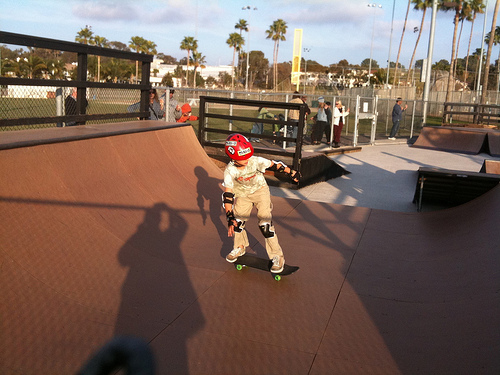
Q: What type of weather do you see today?
A: It is cloudy.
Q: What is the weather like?
A: It is cloudy.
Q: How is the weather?
A: It is cloudy.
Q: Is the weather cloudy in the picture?
A: Yes, it is cloudy.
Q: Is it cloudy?
A: Yes, it is cloudy.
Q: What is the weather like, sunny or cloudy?
A: It is cloudy.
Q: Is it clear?
A: No, it is cloudy.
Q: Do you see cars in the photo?
A: No, there are no cars.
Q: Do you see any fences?
A: Yes, there is a fence.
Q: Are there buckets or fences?
A: Yes, there is a fence.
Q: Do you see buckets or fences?
A: Yes, there is a fence.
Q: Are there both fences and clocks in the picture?
A: No, there is a fence but no clocks.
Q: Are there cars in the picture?
A: No, there are no cars.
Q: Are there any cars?
A: No, there are no cars.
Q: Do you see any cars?
A: No, there are no cars.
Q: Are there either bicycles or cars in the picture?
A: No, there are no cars or bicycles.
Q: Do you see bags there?
A: No, there are no bags.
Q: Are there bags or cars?
A: No, there are no bags or cars.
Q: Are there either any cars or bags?
A: No, there are no bags or cars.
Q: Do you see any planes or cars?
A: No, there are no cars or planes.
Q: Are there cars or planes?
A: No, there are no cars or planes.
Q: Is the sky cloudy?
A: Yes, the sky is cloudy.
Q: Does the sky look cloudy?
A: Yes, the sky is cloudy.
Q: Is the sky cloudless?
A: No, the sky is cloudy.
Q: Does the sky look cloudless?
A: No, the sky is cloudy.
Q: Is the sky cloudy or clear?
A: The sky is cloudy.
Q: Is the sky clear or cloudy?
A: The sky is cloudy.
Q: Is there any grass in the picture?
A: Yes, there is grass.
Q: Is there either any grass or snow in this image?
A: Yes, there is grass.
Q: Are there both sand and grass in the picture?
A: No, there is grass but no sand.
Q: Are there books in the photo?
A: No, there are no books.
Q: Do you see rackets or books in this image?
A: No, there are no books or rackets.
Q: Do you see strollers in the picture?
A: No, there are no strollers.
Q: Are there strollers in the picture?
A: No, there are no strollers.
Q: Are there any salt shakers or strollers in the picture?
A: No, there are no strollers or salt shakers.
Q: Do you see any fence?
A: Yes, there is a fence.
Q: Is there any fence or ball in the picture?
A: Yes, there is a fence.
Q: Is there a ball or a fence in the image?
A: Yes, there is a fence.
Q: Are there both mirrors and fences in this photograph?
A: No, there is a fence but no mirrors.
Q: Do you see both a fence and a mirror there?
A: No, there is a fence but no mirrors.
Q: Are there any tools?
A: No, there are no tools.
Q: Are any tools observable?
A: No, there are no tools.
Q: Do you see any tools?
A: No, there are no tools.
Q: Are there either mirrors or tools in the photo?
A: No, there are no tools or mirrors.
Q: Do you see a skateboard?
A: Yes, there is a skateboard.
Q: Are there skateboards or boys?
A: Yes, there is a skateboard.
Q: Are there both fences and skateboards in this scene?
A: Yes, there are both a skateboard and a fence.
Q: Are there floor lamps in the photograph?
A: No, there are no floor lamps.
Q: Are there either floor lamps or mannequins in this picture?
A: No, there are no floor lamps or mannequins.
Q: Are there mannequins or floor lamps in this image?
A: No, there are no floor lamps or mannequins.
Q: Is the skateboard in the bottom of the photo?
A: Yes, the skateboard is in the bottom of the image.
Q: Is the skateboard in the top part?
A: No, the skateboard is in the bottom of the image.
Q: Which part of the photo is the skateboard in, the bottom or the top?
A: The skateboard is in the bottom of the image.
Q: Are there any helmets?
A: Yes, there is a helmet.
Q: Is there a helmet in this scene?
A: Yes, there is a helmet.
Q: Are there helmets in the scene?
A: Yes, there is a helmet.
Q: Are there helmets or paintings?
A: Yes, there is a helmet.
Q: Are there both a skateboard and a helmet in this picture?
A: Yes, there are both a helmet and a skateboard.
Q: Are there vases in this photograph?
A: No, there are no vases.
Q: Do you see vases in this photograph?
A: No, there are no vases.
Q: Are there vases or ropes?
A: No, there are no vases or ropes.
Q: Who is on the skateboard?
A: The skater is on the skateboard.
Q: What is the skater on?
A: The skater is on the skateboard.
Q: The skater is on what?
A: The skater is on the skateboard.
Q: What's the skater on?
A: The skater is on the skateboard.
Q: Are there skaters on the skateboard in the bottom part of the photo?
A: Yes, there is a skater on the skateboard.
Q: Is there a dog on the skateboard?
A: No, there is a skater on the skateboard.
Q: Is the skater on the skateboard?
A: Yes, the skater is on the skateboard.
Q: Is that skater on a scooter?
A: No, the skater is on the skateboard.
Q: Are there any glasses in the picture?
A: No, there are no glasses.